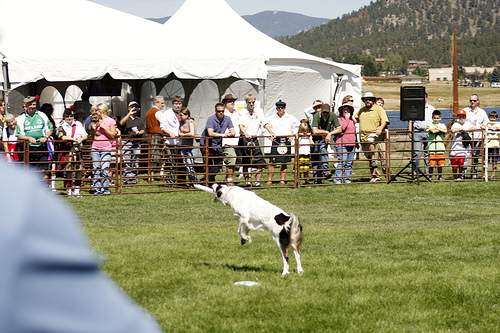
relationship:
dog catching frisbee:
[224, 186, 302, 262] [195, 184, 219, 194]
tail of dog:
[283, 208, 298, 239] [224, 186, 302, 262]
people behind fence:
[55, 91, 203, 125] [111, 141, 164, 198]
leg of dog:
[274, 244, 288, 276] [224, 186, 302, 262]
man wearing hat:
[220, 87, 237, 162] [272, 97, 281, 107]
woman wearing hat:
[19, 93, 38, 107] [272, 97, 281, 107]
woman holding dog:
[19, 93, 38, 107] [224, 186, 302, 262]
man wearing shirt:
[220, 87, 237, 162] [86, 131, 103, 142]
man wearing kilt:
[220, 87, 237, 162] [370, 156, 394, 169]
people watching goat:
[55, 91, 203, 125] [206, 186, 251, 228]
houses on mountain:
[379, 51, 441, 81] [374, 12, 422, 29]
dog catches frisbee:
[224, 186, 302, 262] [195, 184, 219, 194]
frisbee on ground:
[195, 184, 219, 194] [189, 289, 219, 311]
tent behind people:
[127, 5, 228, 66] [55, 91, 203, 125]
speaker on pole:
[400, 83, 428, 118] [437, 53, 474, 86]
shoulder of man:
[1, 192, 83, 231] [220, 87, 237, 162]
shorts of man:
[429, 158, 446, 166] [220, 87, 237, 162]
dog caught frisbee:
[224, 186, 302, 262] [195, 184, 219, 194]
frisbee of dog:
[195, 184, 219, 194] [224, 186, 302, 262]